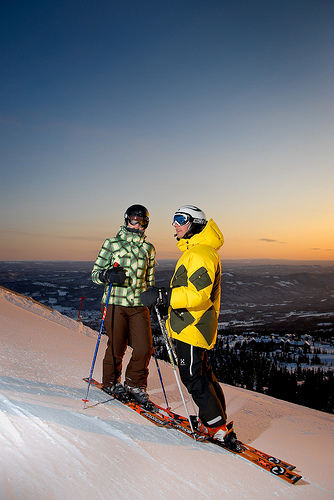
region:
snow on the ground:
[20, 423, 97, 466]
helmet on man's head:
[181, 207, 202, 215]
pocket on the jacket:
[188, 271, 214, 290]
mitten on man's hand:
[105, 266, 125, 283]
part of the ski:
[255, 456, 286, 481]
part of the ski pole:
[155, 316, 184, 394]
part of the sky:
[13, 225, 77, 268]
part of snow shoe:
[203, 422, 225, 438]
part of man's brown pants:
[113, 322, 125, 360]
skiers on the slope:
[73, 202, 303, 486]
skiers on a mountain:
[82, 201, 294, 446]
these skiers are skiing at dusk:
[8, 199, 320, 408]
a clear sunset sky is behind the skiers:
[2, 119, 328, 327]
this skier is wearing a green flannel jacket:
[85, 198, 177, 435]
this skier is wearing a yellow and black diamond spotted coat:
[166, 208, 265, 445]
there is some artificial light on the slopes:
[3, 283, 315, 492]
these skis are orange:
[64, 343, 323, 489]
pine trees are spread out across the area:
[15, 251, 328, 402]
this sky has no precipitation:
[6, 7, 315, 230]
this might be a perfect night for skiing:
[0, 189, 311, 392]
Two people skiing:
[103, 177, 251, 441]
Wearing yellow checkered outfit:
[176, 235, 220, 360]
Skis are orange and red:
[131, 397, 317, 495]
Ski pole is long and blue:
[86, 300, 106, 397]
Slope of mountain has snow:
[2, 293, 244, 498]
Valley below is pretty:
[46, 257, 333, 398]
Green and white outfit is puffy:
[101, 230, 152, 306]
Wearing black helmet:
[121, 202, 155, 235]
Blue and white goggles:
[173, 215, 189, 225]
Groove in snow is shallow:
[20, 407, 72, 454]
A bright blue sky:
[53, 29, 213, 120]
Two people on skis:
[73, 195, 270, 455]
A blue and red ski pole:
[78, 260, 129, 407]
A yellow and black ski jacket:
[166, 199, 235, 353]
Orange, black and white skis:
[79, 368, 308, 482]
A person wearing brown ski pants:
[95, 286, 162, 409]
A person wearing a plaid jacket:
[87, 219, 154, 309]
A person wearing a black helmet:
[106, 196, 163, 247]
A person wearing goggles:
[169, 207, 198, 232]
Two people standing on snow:
[67, 198, 286, 466]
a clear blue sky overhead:
[57, 20, 301, 105]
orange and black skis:
[243, 440, 314, 487]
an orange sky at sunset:
[253, 230, 327, 259]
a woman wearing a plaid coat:
[88, 204, 152, 399]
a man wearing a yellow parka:
[169, 204, 247, 421]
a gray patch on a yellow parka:
[191, 308, 218, 347]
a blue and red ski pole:
[102, 288, 107, 344]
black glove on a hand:
[97, 261, 129, 279]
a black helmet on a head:
[128, 205, 148, 221]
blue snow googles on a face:
[170, 212, 185, 225]